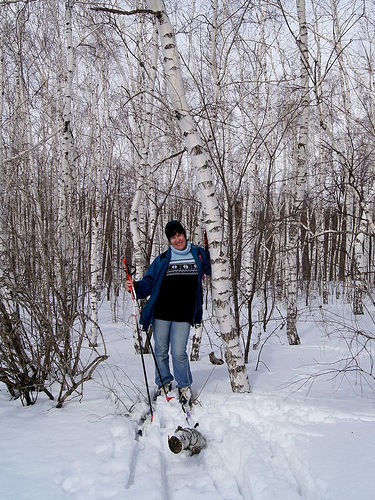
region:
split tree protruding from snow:
[157, 399, 241, 469]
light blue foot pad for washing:
[147, 416, 255, 465]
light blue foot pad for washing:
[154, 411, 223, 487]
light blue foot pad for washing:
[145, 392, 233, 469]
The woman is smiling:
[131, 217, 230, 317]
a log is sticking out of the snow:
[145, 419, 273, 495]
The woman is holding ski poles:
[105, 251, 214, 427]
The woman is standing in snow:
[18, 189, 364, 483]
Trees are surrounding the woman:
[12, 152, 349, 347]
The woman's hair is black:
[156, 220, 202, 265]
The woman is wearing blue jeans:
[144, 315, 224, 436]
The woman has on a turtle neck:
[158, 239, 227, 366]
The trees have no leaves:
[7, 155, 308, 321]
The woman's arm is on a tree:
[134, 224, 312, 332]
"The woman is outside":
[104, 187, 279, 426]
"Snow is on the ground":
[20, 409, 366, 487]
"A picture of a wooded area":
[8, 116, 368, 396]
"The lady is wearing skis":
[111, 197, 252, 440]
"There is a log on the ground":
[153, 413, 239, 463]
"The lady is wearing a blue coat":
[95, 215, 254, 431]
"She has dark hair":
[133, 191, 254, 310]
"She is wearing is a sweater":
[130, 208, 235, 434]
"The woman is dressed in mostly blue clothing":
[122, 204, 248, 415]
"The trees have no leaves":
[26, 127, 355, 386]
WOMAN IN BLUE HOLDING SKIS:
[98, 212, 241, 417]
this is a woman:
[122, 226, 199, 415]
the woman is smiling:
[159, 219, 189, 250]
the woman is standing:
[136, 227, 219, 406]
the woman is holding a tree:
[191, 230, 254, 387]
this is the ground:
[248, 403, 354, 494]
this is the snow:
[255, 385, 327, 468]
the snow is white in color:
[229, 405, 285, 471]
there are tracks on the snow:
[114, 460, 290, 494]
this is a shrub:
[15, 255, 86, 398]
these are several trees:
[38, 11, 339, 168]